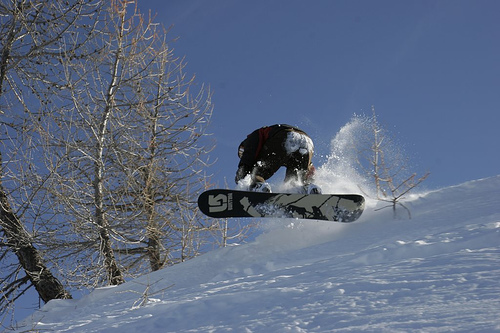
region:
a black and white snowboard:
[193, 185, 371, 227]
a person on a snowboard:
[226, 121, 330, 197]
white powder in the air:
[316, 112, 386, 202]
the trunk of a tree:
[0, 186, 75, 303]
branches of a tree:
[356, 105, 431, 225]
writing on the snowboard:
[225, 187, 237, 214]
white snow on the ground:
[0, 173, 499, 331]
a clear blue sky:
[0, 0, 495, 332]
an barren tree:
[91, 32, 228, 275]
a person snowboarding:
[184, 122, 377, 230]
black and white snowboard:
[196, 183, 381, 234]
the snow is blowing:
[192, 98, 387, 248]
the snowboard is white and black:
[160, 174, 374, 255]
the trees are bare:
[45, 35, 182, 255]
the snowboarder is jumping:
[218, 104, 330, 187]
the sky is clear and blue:
[200, 25, 460, 153]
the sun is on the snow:
[142, 229, 416, 321]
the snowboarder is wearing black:
[200, 97, 320, 185]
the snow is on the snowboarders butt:
[211, 103, 324, 178]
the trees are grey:
[38, 45, 183, 250]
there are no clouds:
[245, 47, 469, 152]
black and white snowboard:
[162, 170, 394, 258]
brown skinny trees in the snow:
[27, 15, 209, 299]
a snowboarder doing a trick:
[165, 98, 419, 274]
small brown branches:
[366, 135, 450, 233]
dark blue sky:
[327, 12, 402, 114]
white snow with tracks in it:
[305, 275, 436, 319]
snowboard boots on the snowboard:
[242, 165, 351, 210]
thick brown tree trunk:
[7, 250, 107, 329]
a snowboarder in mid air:
[139, 81, 439, 261]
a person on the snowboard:
[230, 118, 325, 195]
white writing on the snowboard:
[226, 187, 236, 213]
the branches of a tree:
[341, 100, 435, 230]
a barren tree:
[87, 21, 227, 276]